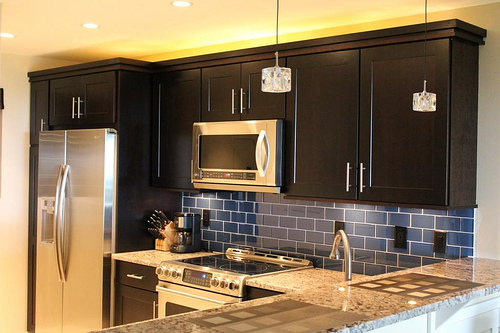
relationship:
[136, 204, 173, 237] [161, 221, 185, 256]
knives in block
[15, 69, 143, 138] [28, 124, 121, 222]
cabinets above fridge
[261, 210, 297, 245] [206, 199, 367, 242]
brick on wall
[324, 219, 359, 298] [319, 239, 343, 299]
faucet on sink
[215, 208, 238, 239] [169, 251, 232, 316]
tile behind stove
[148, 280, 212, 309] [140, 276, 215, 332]
silver oven door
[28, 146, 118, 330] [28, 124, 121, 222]
doors on fridge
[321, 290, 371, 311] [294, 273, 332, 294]
granite counter top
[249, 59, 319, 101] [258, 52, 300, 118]
lights hanging down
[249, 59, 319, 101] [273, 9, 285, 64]
lights on cords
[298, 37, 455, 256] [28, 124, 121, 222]
cabinets above fridge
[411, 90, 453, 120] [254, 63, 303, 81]
cube shaped light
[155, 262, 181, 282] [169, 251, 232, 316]
knobs on stove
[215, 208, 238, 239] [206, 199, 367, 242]
tile on wall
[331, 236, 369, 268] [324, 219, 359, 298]
metal kitchen faucet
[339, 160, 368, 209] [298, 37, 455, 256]
handles on cabinets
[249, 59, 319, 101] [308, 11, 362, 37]
lights in ceiling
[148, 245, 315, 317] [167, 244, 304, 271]
stove has flat top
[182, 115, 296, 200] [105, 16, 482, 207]
microwave under cabinets